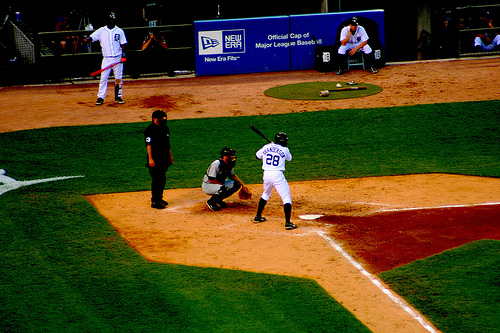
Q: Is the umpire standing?
A: Yes, the umpire is standing.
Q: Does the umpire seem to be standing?
A: Yes, the umpire is standing.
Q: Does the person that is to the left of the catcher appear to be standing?
A: Yes, the umpire is standing.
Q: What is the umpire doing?
A: The umpire is standing.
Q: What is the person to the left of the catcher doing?
A: The umpire is standing.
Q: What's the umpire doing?
A: The umpire is standing.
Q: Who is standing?
A: The umpire is standing.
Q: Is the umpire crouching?
A: No, the umpire is standing.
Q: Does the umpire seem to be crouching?
A: No, the umpire is standing.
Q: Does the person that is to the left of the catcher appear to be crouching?
A: No, the umpire is standing.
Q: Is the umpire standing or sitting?
A: The umpire is standing.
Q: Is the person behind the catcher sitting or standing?
A: The umpire is standing.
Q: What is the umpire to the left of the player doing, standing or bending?
A: The umpire is standing.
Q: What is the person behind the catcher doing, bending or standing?
A: The umpire is standing.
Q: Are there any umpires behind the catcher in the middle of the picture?
A: Yes, there is an umpire behind the catcher.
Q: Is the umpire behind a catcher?
A: Yes, the umpire is behind a catcher.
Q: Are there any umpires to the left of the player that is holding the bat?
A: Yes, there is an umpire to the left of the player.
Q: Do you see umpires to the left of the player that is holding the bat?
A: Yes, there is an umpire to the left of the player.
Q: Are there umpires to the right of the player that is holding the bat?
A: No, the umpire is to the left of the player.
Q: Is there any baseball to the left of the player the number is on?
A: No, there is an umpire to the left of the player.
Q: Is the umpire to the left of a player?
A: Yes, the umpire is to the left of a player.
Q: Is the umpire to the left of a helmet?
A: No, the umpire is to the left of a player.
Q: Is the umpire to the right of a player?
A: No, the umpire is to the left of a player.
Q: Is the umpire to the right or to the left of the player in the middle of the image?
A: The umpire is to the left of the player.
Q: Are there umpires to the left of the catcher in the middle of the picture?
A: Yes, there is an umpire to the left of the catcher.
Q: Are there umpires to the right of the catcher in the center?
A: No, the umpire is to the left of the catcher.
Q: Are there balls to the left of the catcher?
A: No, there is an umpire to the left of the catcher.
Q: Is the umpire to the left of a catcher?
A: Yes, the umpire is to the left of a catcher.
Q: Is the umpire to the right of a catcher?
A: No, the umpire is to the left of a catcher.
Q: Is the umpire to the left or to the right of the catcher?
A: The umpire is to the left of the catcher.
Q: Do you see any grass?
A: Yes, there is grass.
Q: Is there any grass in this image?
A: Yes, there is grass.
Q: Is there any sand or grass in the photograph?
A: Yes, there is grass.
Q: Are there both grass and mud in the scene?
A: No, there is grass but no mud.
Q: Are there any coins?
A: No, there are no coins.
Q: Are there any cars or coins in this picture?
A: No, there are no coins or cars.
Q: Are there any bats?
A: Yes, there is a bat.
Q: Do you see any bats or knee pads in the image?
A: Yes, there is a bat.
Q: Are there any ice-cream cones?
A: No, there are no ice-cream cones.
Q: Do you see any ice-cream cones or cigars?
A: No, there are no ice-cream cones or cigars.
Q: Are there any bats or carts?
A: Yes, there is a bat.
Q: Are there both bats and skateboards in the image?
A: No, there is a bat but no skateboards.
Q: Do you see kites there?
A: No, there are no kites.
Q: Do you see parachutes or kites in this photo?
A: No, there are no kites or parachutes.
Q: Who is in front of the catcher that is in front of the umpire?
A: The player is in front of the catcher.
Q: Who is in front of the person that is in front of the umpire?
A: The player is in front of the catcher.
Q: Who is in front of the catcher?
A: The player is in front of the catcher.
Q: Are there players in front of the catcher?
A: Yes, there is a player in front of the catcher.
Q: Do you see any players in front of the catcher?
A: Yes, there is a player in front of the catcher.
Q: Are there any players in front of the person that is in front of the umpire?
A: Yes, there is a player in front of the catcher.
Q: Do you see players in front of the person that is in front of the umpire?
A: Yes, there is a player in front of the catcher.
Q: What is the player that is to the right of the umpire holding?
A: The player is holding the bat.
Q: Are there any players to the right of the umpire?
A: Yes, there is a player to the right of the umpire.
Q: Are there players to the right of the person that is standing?
A: Yes, there is a player to the right of the umpire.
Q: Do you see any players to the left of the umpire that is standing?
A: No, the player is to the right of the umpire.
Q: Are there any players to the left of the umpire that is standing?
A: No, the player is to the right of the umpire.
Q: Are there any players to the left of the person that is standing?
A: No, the player is to the right of the umpire.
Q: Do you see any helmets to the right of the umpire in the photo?
A: No, there is a player to the right of the umpire.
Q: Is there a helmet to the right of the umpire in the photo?
A: No, there is a player to the right of the umpire.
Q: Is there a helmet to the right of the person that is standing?
A: No, there is a player to the right of the umpire.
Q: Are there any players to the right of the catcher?
A: Yes, there is a player to the right of the catcher.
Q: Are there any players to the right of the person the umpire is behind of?
A: Yes, there is a player to the right of the catcher.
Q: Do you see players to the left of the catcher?
A: No, the player is to the right of the catcher.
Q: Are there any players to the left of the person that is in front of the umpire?
A: No, the player is to the right of the catcher.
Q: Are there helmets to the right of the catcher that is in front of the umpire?
A: No, there is a player to the right of the catcher.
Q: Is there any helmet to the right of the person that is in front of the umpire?
A: No, there is a player to the right of the catcher.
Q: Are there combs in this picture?
A: No, there are no combs.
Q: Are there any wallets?
A: No, there are no wallets.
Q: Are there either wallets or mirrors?
A: No, there are no wallets or mirrors.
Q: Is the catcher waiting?
A: Yes, the catcher is waiting.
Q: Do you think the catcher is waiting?
A: Yes, the catcher is waiting.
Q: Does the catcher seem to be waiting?
A: Yes, the catcher is waiting.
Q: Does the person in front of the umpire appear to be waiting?
A: Yes, the catcher is waiting.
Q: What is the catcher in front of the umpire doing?
A: The catcher is waiting.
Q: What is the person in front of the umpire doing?
A: The catcher is waiting.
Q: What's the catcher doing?
A: The catcher is waiting.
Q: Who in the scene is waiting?
A: The catcher is waiting.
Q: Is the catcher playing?
A: No, the catcher is waiting.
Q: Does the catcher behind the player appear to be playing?
A: No, the catcher is waiting.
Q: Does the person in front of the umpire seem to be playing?
A: No, the catcher is waiting.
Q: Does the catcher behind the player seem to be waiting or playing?
A: The catcher is waiting.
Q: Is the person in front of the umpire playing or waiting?
A: The catcher is waiting.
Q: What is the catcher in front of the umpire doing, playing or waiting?
A: The catcher is waiting.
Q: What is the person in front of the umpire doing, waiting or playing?
A: The catcher is waiting.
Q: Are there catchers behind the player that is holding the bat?
A: Yes, there is a catcher behind the player.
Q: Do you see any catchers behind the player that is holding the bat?
A: Yes, there is a catcher behind the player.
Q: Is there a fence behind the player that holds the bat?
A: No, there is a catcher behind the player.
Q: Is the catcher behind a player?
A: Yes, the catcher is behind a player.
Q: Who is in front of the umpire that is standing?
A: The catcher is in front of the umpire.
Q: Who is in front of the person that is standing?
A: The catcher is in front of the umpire.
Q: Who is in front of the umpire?
A: The catcher is in front of the umpire.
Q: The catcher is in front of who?
A: The catcher is in front of the umpire.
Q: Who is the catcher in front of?
A: The catcher is in front of the umpire.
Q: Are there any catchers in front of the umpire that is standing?
A: Yes, there is a catcher in front of the umpire.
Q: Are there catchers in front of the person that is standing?
A: Yes, there is a catcher in front of the umpire.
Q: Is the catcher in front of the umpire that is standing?
A: Yes, the catcher is in front of the umpire.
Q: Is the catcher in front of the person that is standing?
A: Yes, the catcher is in front of the umpire.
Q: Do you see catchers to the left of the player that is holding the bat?
A: Yes, there is a catcher to the left of the player.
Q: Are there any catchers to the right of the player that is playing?
A: No, the catcher is to the left of the player.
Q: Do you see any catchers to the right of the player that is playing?
A: No, the catcher is to the left of the player.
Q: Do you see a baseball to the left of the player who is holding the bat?
A: No, there is a catcher to the left of the player.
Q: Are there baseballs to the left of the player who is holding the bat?
A: No, there is a catcher to the left of the player.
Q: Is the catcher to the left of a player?
A: Yes, the catcher is to the left of a player.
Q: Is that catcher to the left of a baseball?
A: No, the catcher is to the left of a player.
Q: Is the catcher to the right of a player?
A: No, the catcher is to the left of a player.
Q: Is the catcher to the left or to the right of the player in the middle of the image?
A: The catcher is to the left of the player.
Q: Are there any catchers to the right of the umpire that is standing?
A: Yes, there is a catcher to the right of the umpire.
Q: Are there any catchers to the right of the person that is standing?
A: Yes, there is a catcher to the right of the umpire.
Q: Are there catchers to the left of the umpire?
A: No, the catcher is to the right of the umpire.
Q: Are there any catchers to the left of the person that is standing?
A: No, the catcher is to the right of the umpire.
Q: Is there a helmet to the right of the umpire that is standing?
A: No, there is a catcher to the right of the umpire.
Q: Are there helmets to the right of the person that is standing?
A: No, there is a catcher to the right of the umpire.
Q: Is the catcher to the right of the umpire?
A: Yes, the catcher is to the right of the umpire.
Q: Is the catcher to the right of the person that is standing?
A: Yes, the catcher is to the right of the umpire.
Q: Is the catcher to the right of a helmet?
A: No, the catcher is to the right of the umpire.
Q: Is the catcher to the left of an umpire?
A: No, the catcher is to the right of an umpire.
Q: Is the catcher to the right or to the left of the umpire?
A: The catcher is to the right of the umpire.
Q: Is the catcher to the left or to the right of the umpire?
A: The catcher is to the right of the umpire.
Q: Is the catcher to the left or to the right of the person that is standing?
A: The catcher is to the right of the umpire.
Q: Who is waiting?
A: The player is waiting.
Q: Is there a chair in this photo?
A: Yes, there is a chair.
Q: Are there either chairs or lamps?
A: Yes, there is a chair.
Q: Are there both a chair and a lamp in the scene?
A: No, there is a chair but no lamps.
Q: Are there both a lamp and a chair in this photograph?
A: No, there is a chair but no lamps.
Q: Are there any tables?
A: No, there are no tables.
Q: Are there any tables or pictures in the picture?
A: No, there are no tables or pictures.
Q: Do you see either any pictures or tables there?
A: No, there are no tables or pictures.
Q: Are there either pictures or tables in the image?
A: No, there are no tables or pictures.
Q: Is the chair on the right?
A: Yes, the chair is on the right of the image.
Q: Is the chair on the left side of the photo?
A: No, the chair is on the right of the image.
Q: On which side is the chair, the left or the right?
A: The chair is on the right of the image.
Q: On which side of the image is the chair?
A: The chair is on the right of the image.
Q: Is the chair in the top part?
A: Yes, the chair is in the top of the image.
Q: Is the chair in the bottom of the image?
A: No, the chair is in the top of the image.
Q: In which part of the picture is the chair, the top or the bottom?
A: The chair is in the top of the image.